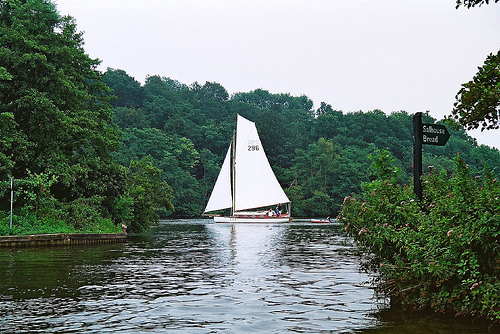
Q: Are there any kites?
A: No, there are no kites.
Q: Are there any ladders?
A: No, there are no ladders.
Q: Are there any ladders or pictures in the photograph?
A: No, there are no ladders or pictures.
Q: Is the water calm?
A: Yes, the water is calm.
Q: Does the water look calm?
A: Yes, the water is calm.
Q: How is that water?
A: The water is calm.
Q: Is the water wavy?
A: No, the water is calm.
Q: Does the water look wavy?
A: No, the water is calm.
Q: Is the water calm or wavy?
A: The water is calm.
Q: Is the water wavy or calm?
A: The water is calm.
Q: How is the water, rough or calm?
A: The water is calm.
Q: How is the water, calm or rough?
A: The water is calm.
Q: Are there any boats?
A: Yes, there is a boat.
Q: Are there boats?
A: Yes, there is a boat.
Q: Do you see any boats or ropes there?
A: Yes, there is a boat.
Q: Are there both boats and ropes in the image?
A: No, there is a boat but no ropes.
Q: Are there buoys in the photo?
A: No, there are no buoys.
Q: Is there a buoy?
A: No, there are no buoys.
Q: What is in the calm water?
A: The boat is in the water.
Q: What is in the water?
A: The boat is in the water.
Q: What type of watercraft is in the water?
A: The watercraft is a boat.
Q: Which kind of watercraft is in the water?
A: The watercraft is a boat.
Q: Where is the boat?
A: The boat is in the water.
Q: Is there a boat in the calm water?
A: Yes, there is a boat in the water.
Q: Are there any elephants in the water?
A: No, there is a boat in the water.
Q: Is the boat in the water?
A: Yes, the boat is in the water.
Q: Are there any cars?
A: No, there are no cars.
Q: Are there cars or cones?
A: No, there are no cars or cones.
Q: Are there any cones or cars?
A: No, there are no cars or cones.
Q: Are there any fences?
A: No, there are no fences.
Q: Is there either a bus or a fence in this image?
A: No, there are no fences or buses.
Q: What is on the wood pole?
A: The sign is on the pole.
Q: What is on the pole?
A: The sign is on the pole.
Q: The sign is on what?
A: The sign is on the pole.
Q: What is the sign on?
A: The sign is on the pole.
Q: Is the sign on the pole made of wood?
A: Yes, the sign is on the pole.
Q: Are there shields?
A: No, there are no shields.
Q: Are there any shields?
A: No, there are no shields.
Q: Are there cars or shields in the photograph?
A: No, there are no shields or cars.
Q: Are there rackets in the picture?
A: No, there are no rackets.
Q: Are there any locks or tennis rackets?
A: No, there are no tennis rackets or locks.